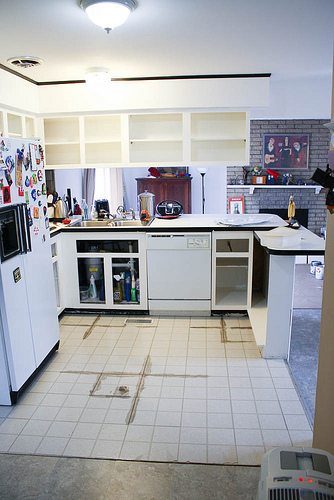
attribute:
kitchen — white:
[0, 0, 327, 469]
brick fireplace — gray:
[225, 118, 329, 238]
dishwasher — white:
[144, 231, 212, 316]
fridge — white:
[2, 130, 78, 414]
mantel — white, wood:
[227, 185, 322, 195]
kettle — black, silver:
[52, 196, 71, 225]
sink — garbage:
[79, 212, 135, 231]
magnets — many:
[1, 141, 48, 240]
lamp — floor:
[193, 167, 209, 210]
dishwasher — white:
[141, 231, 217, 315]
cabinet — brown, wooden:
[127, 161, 224, 227]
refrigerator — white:
[0, 138, 52, 407]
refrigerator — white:
[0, 125, 59, 405]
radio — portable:
[155, 197, 186, 217]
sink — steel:
[63, 205, 161, 239]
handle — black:
[15, 203, 26, 252]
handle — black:
[19, 202, 30, 250]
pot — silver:
[135, 188, 154, 214]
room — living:
[225, 120, 328, 416]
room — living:
[46, 119, 328, 428]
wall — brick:
[250, 120, 324, 131]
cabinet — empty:
[4, 108, 252, 171]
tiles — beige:
[61, 313, 266, 451]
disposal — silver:
[88, 252, 103, 281]